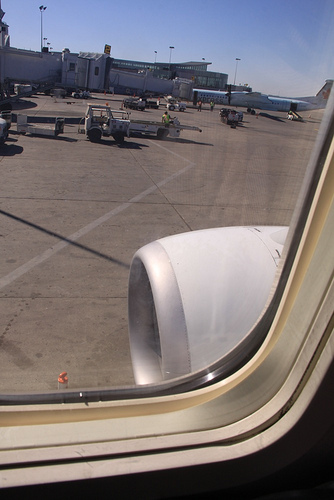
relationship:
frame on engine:
[129, 252, 183, 382] [118, 209, 268, 358]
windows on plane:
[202, 94, 227, 98] [191, 89, 311, 122]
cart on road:
[13, 110, 68, 139] [6, 87, 315, 219]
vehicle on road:
[220, 108, 244, 129] [6, 87, 315, 219]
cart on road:
[125, 97, 145, 112] [6, 87, 315, 219]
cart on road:
[146, 95, 160, 107] [6, 87, 315, 219]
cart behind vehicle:
[13, 110, 68, 139] [68, 87, 90, 98]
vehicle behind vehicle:
[220, 108, 244, 129] [68, 87, 90, 98]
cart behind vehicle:
[125, 97, 145, 112] [164, 95, 187, 112]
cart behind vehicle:
[146, 95, 160, 107] [164, 95, 187, 112]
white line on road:
[133, 133, 194, 164] [6, 130, 315, 396]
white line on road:
[1, 165, 196, 289] [6, 130, 315, 396]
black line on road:
[16, 198, 105, 293] [8, 146, 299, 395]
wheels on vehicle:
[111, 129, 124, 143] [85, 102, 131, 147]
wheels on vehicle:
[88, 124, 103, 141] [85, 102, 131, 147]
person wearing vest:
[160, 108, 172, 125] [160, 112, 170, 123]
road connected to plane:
[6, 87, 315, 219] [187, 78, 327, 118]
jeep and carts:
[82, 104, 130, 147] [122, 93, 189, 112]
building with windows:
[35, 35, 154, 125] [92, 66, 100, 74]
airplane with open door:
[186, 77, 332, 122] [289, 101, 297, 113]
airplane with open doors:
[186, 77, 332, 122] [190, 85, 202, 105]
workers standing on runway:
[210, 99, 215, 111] [54, 90, 288, 157]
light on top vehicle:
[105, 103, 112, 109] [15, 102, 204, 144]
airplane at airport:
[192, 77, 332, 121] [0, 37, 316, 146]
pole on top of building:
[38, 13, 43, 51] [3, 44, 225, 116]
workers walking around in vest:
[196, 99, 215, 112] [196, 100, 200, 102]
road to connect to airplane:
[6, 87, 315, 219] [192, 77, 332, 121]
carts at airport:
[166, 96, 188, 112] [6, 37, 316, 146]